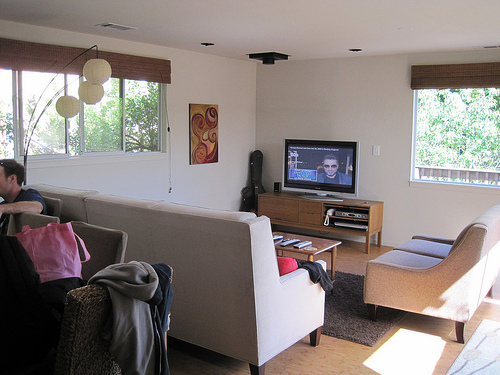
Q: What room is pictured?
A: It is a living room.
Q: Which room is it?
A: It is a living room.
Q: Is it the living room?
A: Yes, it is the living room.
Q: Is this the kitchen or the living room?
A: It is the living room.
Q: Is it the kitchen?
A: No, it is the living room.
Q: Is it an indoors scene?
A: Yes, it is indoors.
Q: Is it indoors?
A: Yes, it is indoors.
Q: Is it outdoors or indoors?
A: It is indoors.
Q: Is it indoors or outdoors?
A: It is indoors.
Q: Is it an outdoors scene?
A: No, it is indoors.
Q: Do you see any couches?
A: Yes, there is a couch.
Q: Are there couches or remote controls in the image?
A: Yes, there is a couch.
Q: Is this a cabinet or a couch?
A: This is a couch.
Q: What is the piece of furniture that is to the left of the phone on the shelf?
A: The piece of furniture is a couch.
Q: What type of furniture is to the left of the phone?
A: The piece of furniture is a couch.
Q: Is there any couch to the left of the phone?
A: Yes, there is a couch to the left of the phone.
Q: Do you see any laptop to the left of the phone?
A: No, there is a couch to the left of the phone.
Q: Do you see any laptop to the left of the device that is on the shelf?
A: No, there is a couch to the left of the phone.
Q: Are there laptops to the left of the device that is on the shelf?
A: No, there is a couch to the left of the phone.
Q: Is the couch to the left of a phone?
A: Yes, the couch is to the left of a phone.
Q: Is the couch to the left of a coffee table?
A: No, the couch is to the left of a phone.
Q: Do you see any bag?
A: Yes, there is a bag.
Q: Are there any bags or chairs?
A: Yes, there is a bag.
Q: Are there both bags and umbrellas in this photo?
A: No, there is a bag but no umbrellas.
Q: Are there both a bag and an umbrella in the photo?
A: No, there is a bag but no umbrellas.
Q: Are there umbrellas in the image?
A: No, there are no umbrellas.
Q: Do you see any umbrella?
A: No, there are no umbrellas.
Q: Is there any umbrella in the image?
A: No, there are no umbrellas.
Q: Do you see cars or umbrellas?
A: No, there are no umbrellas or cars.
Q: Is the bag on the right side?
A: No, the bag is on the left of the image.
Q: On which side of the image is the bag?
A: The bag is on the left of the image.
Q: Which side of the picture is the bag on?
A: The bag is on the left of the image.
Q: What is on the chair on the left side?
A: The bag is on the chair.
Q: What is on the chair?
A: The bag is on the chair.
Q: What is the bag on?
A: The bag is on the chair.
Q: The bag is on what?
A: The bag is on the chair.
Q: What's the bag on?
A: The bag is on the chair.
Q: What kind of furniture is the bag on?
A: The bag is on the chair.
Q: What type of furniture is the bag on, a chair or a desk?
A: The bag is on a chair.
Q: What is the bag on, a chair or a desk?
A: The bag is on a chair.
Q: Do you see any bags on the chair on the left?
A: Yes, there is a bag on the chair.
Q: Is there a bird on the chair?
A: No, there is a bag on the chair.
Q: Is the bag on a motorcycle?
A: No, the bag is on a chair.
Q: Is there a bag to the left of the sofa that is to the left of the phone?
A: Yes, there is a bag to the left of the sofa.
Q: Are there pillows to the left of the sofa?
A: No, there is a bag to the left of the sofa.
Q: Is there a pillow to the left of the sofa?
A: No, there is a bag to the left of the sofa.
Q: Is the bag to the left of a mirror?
A: No, the bag is to the left of a sofa.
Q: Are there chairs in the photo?
A: Yes, there is a chair.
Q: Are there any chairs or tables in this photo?
A: Yes, there is a chair.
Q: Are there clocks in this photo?
A: No, there are no clocks.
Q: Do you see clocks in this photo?
A: No, there are no clocks.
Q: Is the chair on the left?
A: Yes, the chair is on the left of the image.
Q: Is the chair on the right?
A: No, the chair is on the left of the image.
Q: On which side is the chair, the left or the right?
A: The chair is on the left of the image.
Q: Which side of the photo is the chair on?
A: The chair is on the left of the image.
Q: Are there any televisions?
A: Yes, there is a television.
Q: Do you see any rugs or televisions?
A: Yes, there is a television.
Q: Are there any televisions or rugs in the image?
A: Yes, there is a television.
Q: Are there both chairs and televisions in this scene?
A: Yes, there are both a television and a chair.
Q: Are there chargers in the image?
A: No, there are no chargers.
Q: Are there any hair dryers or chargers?
A: No, there are no chargers or hair dryers.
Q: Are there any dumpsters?
A: No, there are no dumpsters.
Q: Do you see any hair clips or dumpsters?
A: No, there are no dumpsters or hair clips.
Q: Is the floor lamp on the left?
A: Yes, the floor lamp is on the left of the image.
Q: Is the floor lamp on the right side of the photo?
A: No, the floor lamp is on the left of the image.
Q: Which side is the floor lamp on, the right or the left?
A: The floor lamp is on the left of the image.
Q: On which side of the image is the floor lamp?
A: The floor lamp is on the left of the image.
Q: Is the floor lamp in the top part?
A: Yes, the floor lamp is in the top of the image.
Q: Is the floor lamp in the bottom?
A: No, the floor lamp is in the top of the image.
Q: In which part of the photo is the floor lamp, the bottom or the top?
A: The floor lamp is in the top of the image.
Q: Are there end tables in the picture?
A: No, there are no end tables.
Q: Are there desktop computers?
A: No, there are no desktop computers.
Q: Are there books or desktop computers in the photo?
A: No, there are no desktop computers or books.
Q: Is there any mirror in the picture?
A: No, there are no mirrors.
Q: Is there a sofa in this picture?
A: Yes, there is a sofa.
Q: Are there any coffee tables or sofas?
A: Yes, there is a sofa.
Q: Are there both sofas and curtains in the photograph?
A: No, there is a sofa but no curtains.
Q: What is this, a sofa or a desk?
A: This is a sofa.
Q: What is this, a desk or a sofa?
A: This is a sofa.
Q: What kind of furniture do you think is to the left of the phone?
A: The piece of furniture is a sofa.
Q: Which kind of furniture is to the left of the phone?
A: The piece of furniture is a sofa.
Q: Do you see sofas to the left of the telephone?
A: Yes, there is a sofa to the left of the telephone.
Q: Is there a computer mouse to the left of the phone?
A: No, there is a sofa to the left of the phone.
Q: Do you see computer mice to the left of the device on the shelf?
A: No, there is a sofa to the left of the phone.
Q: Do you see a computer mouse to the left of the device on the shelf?
A: No, there is a sofa to the left of the phone.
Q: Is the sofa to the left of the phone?
A: Yes, the sofa is to the left of the phone.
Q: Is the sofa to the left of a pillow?
A: No, the sofa is to the left of the phone.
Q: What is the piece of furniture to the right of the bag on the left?
A: The piece of furniture is a sofa.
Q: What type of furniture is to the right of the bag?
A: The piece of furniture is a sofa.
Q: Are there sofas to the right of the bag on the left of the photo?
A: Yes, there is a sofa to the right of the bag.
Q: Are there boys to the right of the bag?
A: No, there is a sofa to the right of the bag.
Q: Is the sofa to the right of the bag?
A: Yes, the sofa is to the right of the bag.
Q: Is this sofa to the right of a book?
A: No, the sofa is to the right of the bag.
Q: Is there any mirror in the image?
A: No, there are no mirrors.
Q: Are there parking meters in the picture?
A: No, there are no parking meters.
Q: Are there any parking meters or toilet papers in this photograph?
A: No, there are no parking meters or toilet papers.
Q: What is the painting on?
A: The painting is on the wall.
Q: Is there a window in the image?
A: Yes, there are windows.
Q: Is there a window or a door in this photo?
A: Yes, there are windows.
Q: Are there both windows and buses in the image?
A: No, there are windows but no buses.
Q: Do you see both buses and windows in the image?
A: No, there are windows but no buses.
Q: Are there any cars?
A: No, there are no cars.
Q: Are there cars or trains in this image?
A: No, there are no cars or trains.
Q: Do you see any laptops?
A: No, there are no laptops.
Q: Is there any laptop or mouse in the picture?
A: No, there are no laptops or computer mice.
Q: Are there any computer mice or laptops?
A: No, there are no laptops or computer mice.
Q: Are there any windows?
A: Yes, there are windows.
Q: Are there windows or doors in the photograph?
A: Yes, there are windows.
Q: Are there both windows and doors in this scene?
A: No, there are windows but no doors.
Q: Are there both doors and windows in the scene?
A: No, there are windows but no doors.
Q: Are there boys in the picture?
A: No, there are no boys.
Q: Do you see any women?
A: No, there are no women.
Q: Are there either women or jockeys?
A: No, there are no women or jockeys.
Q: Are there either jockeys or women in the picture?
A: No, there are no women or jockeys.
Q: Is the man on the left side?
A: Yes, the man is on the left of the image.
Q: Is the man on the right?
A: No, the man is on the left of the image.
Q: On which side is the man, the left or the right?
A: The man is on the left of the image.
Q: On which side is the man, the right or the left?
A: The man is on the left of the image.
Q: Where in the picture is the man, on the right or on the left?
A: The man is on the left of the image.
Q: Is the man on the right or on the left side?
A: The man is on the left of the image.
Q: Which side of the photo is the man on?
A: The man is on the left of the image.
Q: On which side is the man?
A: The man is on the left of the image.